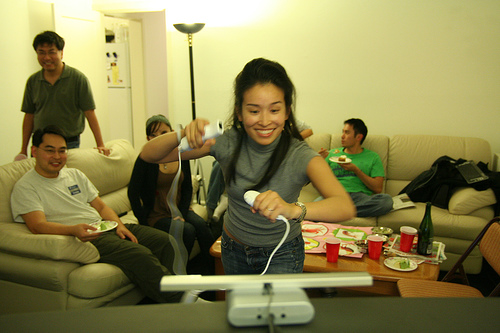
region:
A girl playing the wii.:
[125, 58, 392, 283]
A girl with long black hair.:
[189, 54, 366, 289]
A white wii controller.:
[164, 114, 289, 257]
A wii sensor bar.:
[159, 275, 367, 292]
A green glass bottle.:
[411, 206, 432, 261]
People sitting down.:
[12, 90, 401, 255]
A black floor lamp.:
[167, 18, 218, 126]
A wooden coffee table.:
[287, 213, 437, 279]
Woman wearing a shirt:
[211, 120, 326, 246]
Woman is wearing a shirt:
[202, 117, 323, 252]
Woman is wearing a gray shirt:
[206, 109, 325, 252]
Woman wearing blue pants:
[216, 223, 308, 283]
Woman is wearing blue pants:
[214, 220, 314, 277]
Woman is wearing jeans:
[215, 221, 310, 276]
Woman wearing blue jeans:
[217, 220, 310, 280]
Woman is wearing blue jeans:
[215, 218, 309, 278]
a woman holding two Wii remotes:
[161, 60, 338, 265]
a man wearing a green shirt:
[318, 120, 385, 196]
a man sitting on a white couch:
[302, 120, 492, 252]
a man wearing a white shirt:
[18, 129, 113, 234]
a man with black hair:
[26, 34, 68, 75]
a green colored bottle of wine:
[414, 200, 435, 259]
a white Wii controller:
[176, 114, 226, 147]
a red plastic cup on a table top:
[323, 238, 340, 271]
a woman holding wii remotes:
[165, 48, 349, 279]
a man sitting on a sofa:
[15, 127, 156, 292]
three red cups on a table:
[310, 211, 419, 278]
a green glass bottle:
[414, 200, 443, 262]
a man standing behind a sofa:
[16, 24, 117, 161]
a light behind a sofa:
[166, 14, 216, 129]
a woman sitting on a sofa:
[126, 104, 208, 266]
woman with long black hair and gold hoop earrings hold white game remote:
[137, 58, 354, 273]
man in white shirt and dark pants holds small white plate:
[10, 125, 211, 305]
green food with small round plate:
[382, 254, 417, 269]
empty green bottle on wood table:
[416, 202, 433, 254]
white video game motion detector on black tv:
[158, 270, 373, 325]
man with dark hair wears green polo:
[15, 31, 110, 156]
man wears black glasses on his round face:
[30, 124, 68, 176]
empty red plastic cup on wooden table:
[366, 234, 383, 257]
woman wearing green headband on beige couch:
[127, 114, 212, 274]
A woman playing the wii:
[141, 54, 410, 306]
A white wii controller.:
[171, 117, 315, 269]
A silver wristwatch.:
[293, 199, 312, 230]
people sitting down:
[2, 99, 423, 259]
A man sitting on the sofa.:
[308, 108, 400, 226]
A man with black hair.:
[319, 105, 396, 225]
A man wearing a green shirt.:
[309, 116, 399, 216]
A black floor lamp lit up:
[171, 17, 225, 122]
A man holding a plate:
[30, 128, 165, 269]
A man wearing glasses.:
[14, 111, 186, 294]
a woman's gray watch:
[290, 200, 307, 222]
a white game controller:
[238, 188, 283, 222]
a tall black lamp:
[173, 21, 205, 123]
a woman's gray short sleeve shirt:
[191, 119, 319, 247]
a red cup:
[323, 235, 343, 264]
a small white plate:
[85, 215, 122, 232]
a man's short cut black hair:
[30, 29, 70, 48]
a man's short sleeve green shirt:
[315, 143, 390, 190]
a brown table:
[299, 242, 439, 299]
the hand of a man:
[112, 220, 144, 243]